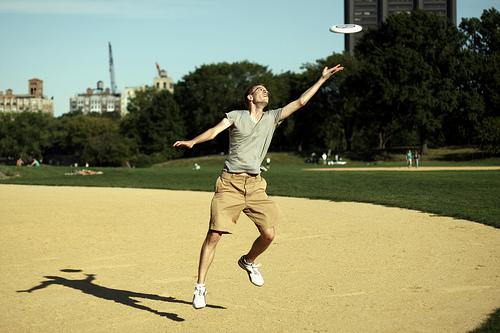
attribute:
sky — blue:
[0, 2, 337, 65]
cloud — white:
[8, 0, 106, 22]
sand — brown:
[9, 196, 492, 333]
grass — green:
[19, 162, 499, 206]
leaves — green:
[411, 29, 434, 46]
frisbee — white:
[325, 21, 370, 42]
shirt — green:
[406, 152, 414, 161]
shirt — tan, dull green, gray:
[226, 110, 283, 177]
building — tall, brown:
[344, 1, 458, 160]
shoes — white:
[190, 262, 266, 312]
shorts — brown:
[205, 170, 287, 241]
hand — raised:
[320, 60, 347, 84]